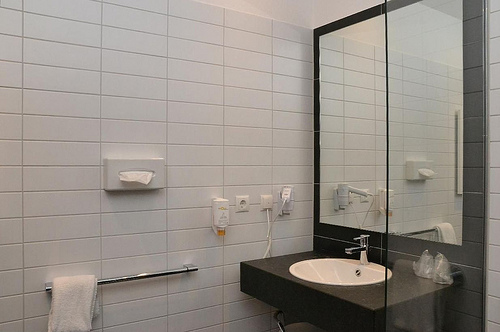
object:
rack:
[44, 264, 199, 296]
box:
[102, 155, 166, 191]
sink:
[289, 258, 392, 286]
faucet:
[345, 234, 370, 264]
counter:
[239, 248, 461, 327]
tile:
[100, 93, 169, 121]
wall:
[385, 0, 500, 332]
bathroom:
[1, 0, 498, 332]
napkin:
[118, 171, 154, 186]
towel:
[49, 274, 97, 332]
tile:
[23, 12, 103, 47]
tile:
[21, 61, 103, 93]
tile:
[21, 34, 102, 70]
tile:
[99, 48, 169, 77]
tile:
[168, 113, 228, 145]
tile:
[103, 212, 181, 248]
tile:
[21, 188, 91, 226]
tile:
[25, 225, 93, 267]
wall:
[0, 0, 317, 332]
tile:
[28, 108, 105, 142]